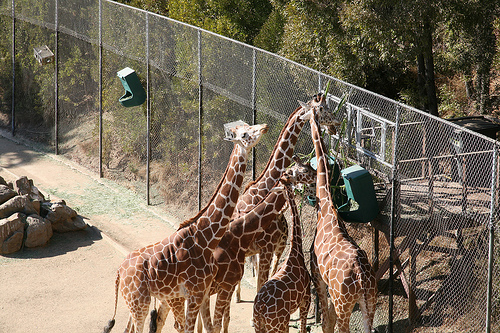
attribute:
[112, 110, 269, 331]
giraffe — young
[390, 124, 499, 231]
deck — Small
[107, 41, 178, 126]
bucket — Green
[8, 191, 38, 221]
rock — edge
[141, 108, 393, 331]
giraffes — African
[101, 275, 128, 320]
tail — part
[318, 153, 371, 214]
bins — green, feeding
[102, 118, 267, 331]
giraffe — metal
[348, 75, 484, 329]
platform — Wooden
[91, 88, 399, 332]
giraffes — five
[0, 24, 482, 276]
fence — tall, metal, wire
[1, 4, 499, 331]
fence — tall 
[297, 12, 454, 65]
trees — Green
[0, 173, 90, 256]
pile — Large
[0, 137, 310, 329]
floor — flat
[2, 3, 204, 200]
metal fence — wire